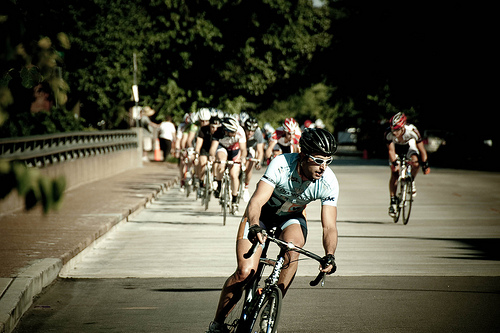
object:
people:
[177, 104, 313, 196]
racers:
[142, 127, 419, 333]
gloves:
[318, 253, 337, 274]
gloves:
[246, 224, 261, 244]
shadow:
[152, 286, 222, 291]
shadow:
[125, 216, 222, 226]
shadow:
[307, 217, 392, 224]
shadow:
[338, 235, 498, 242]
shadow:
[428, 239, 498, 263]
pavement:
[15, 163, 497, 328]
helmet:
[282, 116, 299, 134]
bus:
[151, 105, 333, 297]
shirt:
[261, 153, 340, 215]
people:
[271, 117, 299, 160]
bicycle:
[199, 155, 218, 213]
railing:
[2, 128, 140, 215]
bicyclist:
[205, 127, 340, 333]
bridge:
[2, 121, 494, 331]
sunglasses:
[302, 152, 335, 167]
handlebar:
[239, 226, 267, 259]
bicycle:
[389, 157, 419, 224]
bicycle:
[211, 160, 239, 225]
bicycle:
[177, 147, 194, 199]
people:
[386, 110, 431, 197]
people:
[215, 115, 246, 205]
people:
[194, 117, 225, 197]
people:
[179, 112, 199, 190]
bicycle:
[209, 223, 335, 333]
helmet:
[386, 113, 408, 131]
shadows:
[118, 171, 203, 216]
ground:
[23, 150, 496, 329]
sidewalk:
[1, 167, 186, 330]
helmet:
[300, 127, 337, 158]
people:
[158, 99, 428, 333]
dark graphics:
[262, 163, 334, 214]